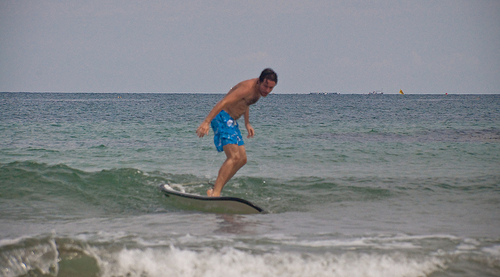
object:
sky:
[5, 1, 497, 92]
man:
[194, 65, 280, 197]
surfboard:
[159, 177, 268, 218]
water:
[6, 93, 498, 273]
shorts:
[204, 109, 252, 152]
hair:
[260, 69, 281, 83]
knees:
[225, 151, 244, 170]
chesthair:
[244, 97, 258, 107]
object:
[392, 84, 410, 97]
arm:
[192, 91, 243, 130]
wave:
[9, 209, 473, 275]